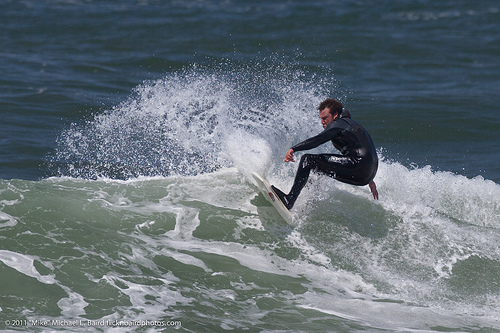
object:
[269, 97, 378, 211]
man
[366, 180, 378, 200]
hand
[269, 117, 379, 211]
body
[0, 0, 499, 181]
ripples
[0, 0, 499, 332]
surface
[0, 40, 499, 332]
wave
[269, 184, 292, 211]
feet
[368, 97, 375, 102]
water drops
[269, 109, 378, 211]
wetsuit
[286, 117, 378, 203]
costume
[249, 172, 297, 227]
board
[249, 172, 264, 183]
edge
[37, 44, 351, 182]
splash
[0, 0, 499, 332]
water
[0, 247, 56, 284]
foam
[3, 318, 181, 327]
graphic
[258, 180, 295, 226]
edge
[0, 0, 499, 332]
air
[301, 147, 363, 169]
reflection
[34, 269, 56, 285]
part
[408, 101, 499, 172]
part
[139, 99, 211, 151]
part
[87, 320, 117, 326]
part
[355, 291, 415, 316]
part